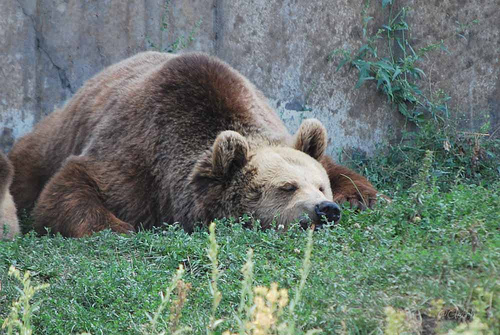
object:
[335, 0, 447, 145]
weeds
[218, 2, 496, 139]
wall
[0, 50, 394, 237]
bear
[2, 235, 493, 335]
grass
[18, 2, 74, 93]
crack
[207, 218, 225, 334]
weeds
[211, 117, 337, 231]
head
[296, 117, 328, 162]
ear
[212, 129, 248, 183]
ear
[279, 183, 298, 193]
eye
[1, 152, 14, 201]
fur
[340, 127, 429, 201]
weeds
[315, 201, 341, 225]
nose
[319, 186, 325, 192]
left eye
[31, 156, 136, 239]
right-leg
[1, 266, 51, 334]
weeds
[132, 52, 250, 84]
hump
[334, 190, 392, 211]
paw